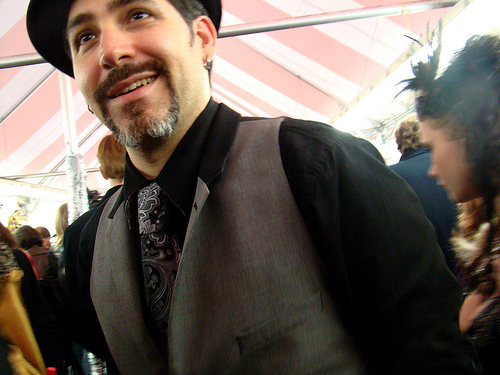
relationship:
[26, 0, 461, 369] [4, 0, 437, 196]
man under a tent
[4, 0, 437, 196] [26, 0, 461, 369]
tent above man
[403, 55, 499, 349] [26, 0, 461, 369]
woman next to man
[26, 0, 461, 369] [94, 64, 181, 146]
man has a goatee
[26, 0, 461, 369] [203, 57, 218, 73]
man wearing earring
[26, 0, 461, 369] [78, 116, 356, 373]
man wearing a vest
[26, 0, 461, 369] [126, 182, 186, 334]
man wearing a tie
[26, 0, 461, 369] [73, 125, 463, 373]
man wearing a shirt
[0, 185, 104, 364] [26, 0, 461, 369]
crowd behind man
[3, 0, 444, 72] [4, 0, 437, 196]
pole to tent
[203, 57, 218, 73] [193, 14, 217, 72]
earring in ear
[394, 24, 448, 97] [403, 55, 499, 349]
feathers on woman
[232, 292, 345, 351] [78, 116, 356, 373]
pocket on vest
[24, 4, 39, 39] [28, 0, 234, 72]
rim of hat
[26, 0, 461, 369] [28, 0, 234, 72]
man wearing a hat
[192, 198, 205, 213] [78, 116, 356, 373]
button hole on vest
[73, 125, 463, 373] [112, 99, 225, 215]
shirt has collar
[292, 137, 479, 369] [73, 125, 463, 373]
sleeve of shirt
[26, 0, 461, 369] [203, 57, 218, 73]
man wearing an earring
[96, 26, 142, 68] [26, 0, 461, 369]
nose of man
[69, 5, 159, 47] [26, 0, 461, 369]
eyes of man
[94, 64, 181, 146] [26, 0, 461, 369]
goatee on man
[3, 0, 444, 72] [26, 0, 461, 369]
pole above man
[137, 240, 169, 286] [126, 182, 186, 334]
design on tie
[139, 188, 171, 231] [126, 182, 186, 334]
knot of tie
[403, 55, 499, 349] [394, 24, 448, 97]
woman has feathers